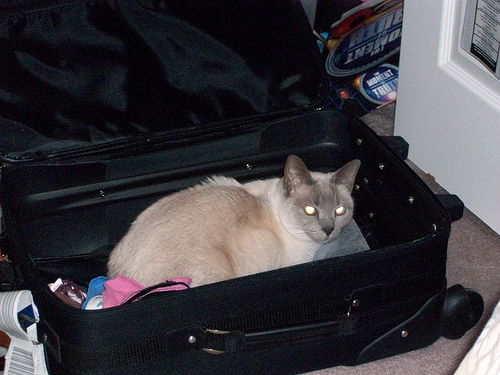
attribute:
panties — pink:
[98, 273, 190, 308]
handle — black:
[202, 304, 357, 352]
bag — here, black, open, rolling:
[2, 2, 478, 368]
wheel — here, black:
[446, 282, 481, 342]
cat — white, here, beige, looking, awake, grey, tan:
[94, 154, 370, 291]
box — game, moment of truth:
[312, 1, 405, 118]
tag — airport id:
[2, 287, 55, 374]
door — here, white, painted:
[386, 2, 500, 236]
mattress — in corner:
[450, 299, 500, 374]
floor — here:
[278, 94, 499, 375]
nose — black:
[325, 226, 333, 234]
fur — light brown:
[113, 160, 360, 289]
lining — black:
[120, 280, 191, 304]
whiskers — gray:
[288, 212, 354, 240]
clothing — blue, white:
[81, 272, 112, 311]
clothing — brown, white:
[44, 273, 86, 309]